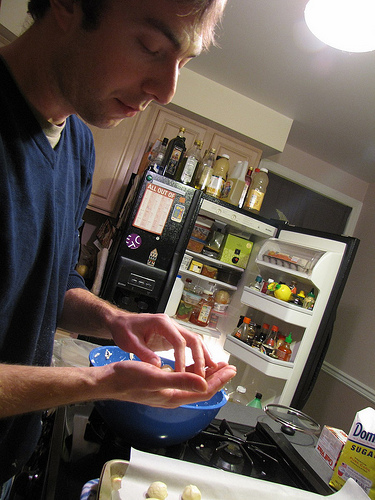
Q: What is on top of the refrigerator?
A: Bottles.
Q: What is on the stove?
A: A blue bowl.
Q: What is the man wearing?
A: A blue shirt.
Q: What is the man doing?
A: Cooking.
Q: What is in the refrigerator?
A: Food.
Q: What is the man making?
A: Sugar cookies.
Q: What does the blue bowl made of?
A: Plastic.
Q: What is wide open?
A: The fridge door.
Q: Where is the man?
A: Standing over the stove.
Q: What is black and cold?
A: The fridge.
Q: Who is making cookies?
A: The man.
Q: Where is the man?
A: In the kitchen.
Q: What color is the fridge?
A: Black.